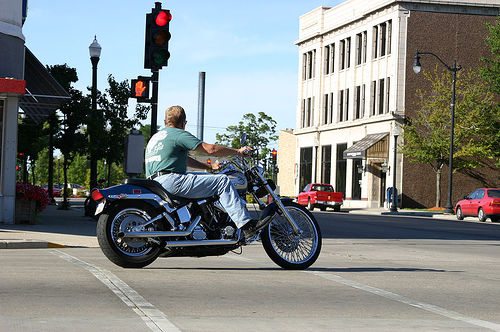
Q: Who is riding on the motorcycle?
A: A man.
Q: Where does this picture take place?
A: On a road.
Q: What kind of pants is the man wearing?
A: Jeans.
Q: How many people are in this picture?
A: One.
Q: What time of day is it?
A: Daytime.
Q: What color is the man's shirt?
A: Green and white.